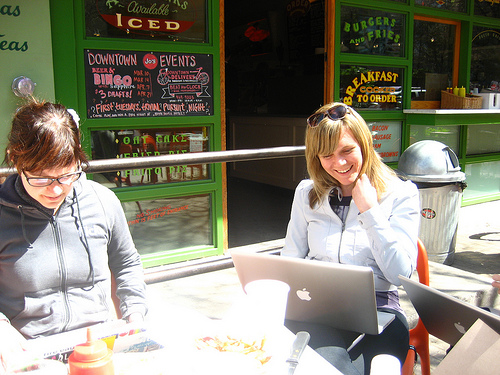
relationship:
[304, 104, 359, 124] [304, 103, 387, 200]
sunlasses on top of head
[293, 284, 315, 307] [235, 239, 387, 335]
apple in front of laptop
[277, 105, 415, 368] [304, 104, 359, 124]
woman have on sunlasses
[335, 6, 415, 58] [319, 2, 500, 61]
sign in window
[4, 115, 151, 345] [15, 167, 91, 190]
woman wearing glasses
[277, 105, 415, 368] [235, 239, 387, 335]
woman has laptop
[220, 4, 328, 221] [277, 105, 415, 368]
door near woman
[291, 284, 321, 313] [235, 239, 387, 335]
logo in front of laptop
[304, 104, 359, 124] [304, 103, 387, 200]
sunlasses on head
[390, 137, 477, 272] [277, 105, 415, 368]
garbage can behind woman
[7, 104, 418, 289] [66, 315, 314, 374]
ladies sitting at table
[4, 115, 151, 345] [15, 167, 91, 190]
girl wearing glasses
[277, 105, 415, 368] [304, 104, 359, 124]
woman wearing sunlasses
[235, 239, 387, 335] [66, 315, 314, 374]
laptop on top of table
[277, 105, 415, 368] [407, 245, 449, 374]
woman sitting on chair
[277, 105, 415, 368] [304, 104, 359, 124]
woman with sunlasses